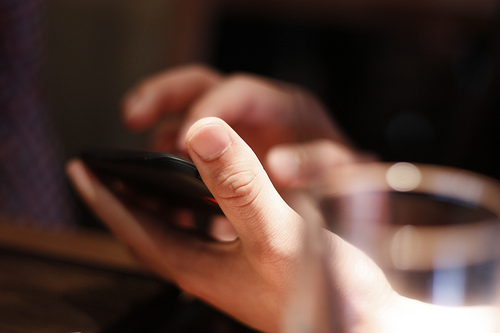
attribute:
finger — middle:
[168, 112, 352, 312]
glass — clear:
[307, 145, 499, 312]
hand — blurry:
[118, 55, 418, 297]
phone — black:
[84, 151, 226, 213]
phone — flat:
[80, 142, 227, 210]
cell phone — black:
[68, 142, 238, 218]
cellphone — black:
[76, 132, 216, 202]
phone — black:
[65, 118, 240, 216]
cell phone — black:
[63, 128, 261, 252]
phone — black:
[67, 145, 255, 222]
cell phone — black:
[77, 144, 236, 214]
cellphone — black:
[78, 135, 226, 205]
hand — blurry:
[119, 62, 381, 190]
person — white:
[58, 62, 498, 332]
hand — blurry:
[64, 115, 390, 332]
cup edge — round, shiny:
[297, 158, 498, 271]